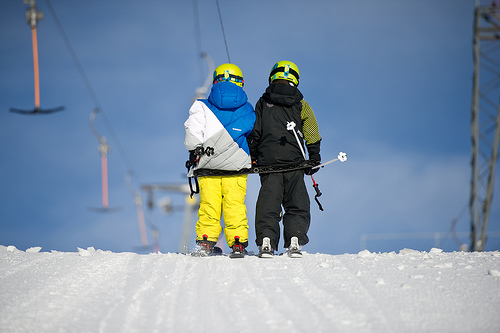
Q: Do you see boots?
A: Yes, there are boots.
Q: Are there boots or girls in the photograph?
A: Yes, there are boots.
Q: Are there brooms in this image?
A: No, there are no brooms.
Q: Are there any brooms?
A: No, there are no brooms.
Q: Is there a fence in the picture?
A: No, there are no fences.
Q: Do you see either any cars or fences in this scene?
A: No, there are no fences or cars.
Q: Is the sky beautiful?
A: Yes, the sky is beautiful.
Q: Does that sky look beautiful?
A: Yes, the sky is beautiful.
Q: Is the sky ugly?
A: No, the sky is beautiful.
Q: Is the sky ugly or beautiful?
A: The sky is beautiful.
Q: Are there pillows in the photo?
A: No, there are no pillows.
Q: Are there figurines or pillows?
A: No, there are no pillows or figurines.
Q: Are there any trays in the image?
A: No, there are no trays.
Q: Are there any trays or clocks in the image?
A: No, there are no trays or clocks.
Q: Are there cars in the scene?
A: No, there are no cars.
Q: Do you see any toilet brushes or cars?
A: No, there are no cars or toilet brushes.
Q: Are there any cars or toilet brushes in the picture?
A: No, there are no cars or toilet brushes.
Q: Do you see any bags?
A: No, there are no bags.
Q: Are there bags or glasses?
A: No, there are no bags or glasses.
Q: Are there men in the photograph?
A: No, there are no men.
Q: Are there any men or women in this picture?
A: No, there are no men or women.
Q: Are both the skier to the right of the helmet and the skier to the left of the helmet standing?
A: Yes, both the skier and the skier are standing.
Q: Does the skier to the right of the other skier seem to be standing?
A: Yes, the skier is standing.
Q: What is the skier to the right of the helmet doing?
A: The skier is standing.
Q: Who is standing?
A: The skier is standing.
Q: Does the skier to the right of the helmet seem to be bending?
A: No, the skier is standing.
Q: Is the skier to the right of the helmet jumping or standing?
A: The skier is standing.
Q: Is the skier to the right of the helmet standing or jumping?
A: The skier is standing.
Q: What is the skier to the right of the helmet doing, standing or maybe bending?
A: The skier is standing.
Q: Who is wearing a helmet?
A: The skier is wearing a helmet.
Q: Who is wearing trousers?
A: The skier is wearing trousers.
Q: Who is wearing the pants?
A: The skier is wearing trousers.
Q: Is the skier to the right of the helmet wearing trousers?
A: Yes, the skier is wearing trousers.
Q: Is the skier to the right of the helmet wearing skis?
A: No, the skier is wearing trousers.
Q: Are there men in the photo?
A: No, there are no men.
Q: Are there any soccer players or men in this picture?
A: No, there are no men or soccer players.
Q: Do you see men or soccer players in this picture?
A: No, there are no men or soccer players.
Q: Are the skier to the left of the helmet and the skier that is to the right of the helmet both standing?
A: Yes, both the skier and the skier are standing.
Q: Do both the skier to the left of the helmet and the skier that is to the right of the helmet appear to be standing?
A: Yes, both the skier and the skier are standing.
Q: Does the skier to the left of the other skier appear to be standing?
A: Yes, the skier is standing.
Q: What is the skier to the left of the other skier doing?
A: The skier is standing.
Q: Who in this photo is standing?
A: The skier is standing.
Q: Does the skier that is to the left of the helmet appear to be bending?
A: No, the skier is standing.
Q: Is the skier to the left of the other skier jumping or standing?
A: The skier is standing.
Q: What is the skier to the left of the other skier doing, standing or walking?
A: The skier is standing.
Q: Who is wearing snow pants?
A: The skier is wearing snow pants.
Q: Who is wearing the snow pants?
A: The skier is wearing snow pants.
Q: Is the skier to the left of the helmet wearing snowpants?
A: Yes, the skier is wearing snowpants.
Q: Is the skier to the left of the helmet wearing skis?
A: No, the skier is wearing snowpants.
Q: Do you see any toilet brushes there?
A: No, there are no toilet brushes.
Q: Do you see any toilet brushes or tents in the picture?
A: No, there are no toilet brushes or tents.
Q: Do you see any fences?
A: No, there are no fences.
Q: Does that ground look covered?
A: Yes, the ground is covered.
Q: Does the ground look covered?
A: Yes, the ground is covered.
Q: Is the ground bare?
A: No, the ground is covered.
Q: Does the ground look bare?
A: No, the ground is covered.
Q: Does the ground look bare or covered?
A: The ground is covered.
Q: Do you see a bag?
A: No, there are no bags.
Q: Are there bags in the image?
A: No, there are no bags.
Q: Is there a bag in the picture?
A: No, there are no bags.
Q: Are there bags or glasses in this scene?
A: No, there are no bags or glasses.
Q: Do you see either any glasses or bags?
A: No, there are no bags or glasses.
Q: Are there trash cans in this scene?
A: No, there are no trash cans.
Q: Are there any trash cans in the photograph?
A: No, there are no trash cans.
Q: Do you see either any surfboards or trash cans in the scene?
A: No, there are no trash cans or surfboards.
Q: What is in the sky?
A: The clouds are in the sky.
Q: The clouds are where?
A: The clouds are in the sky.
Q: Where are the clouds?
A: The clouds are in the sky.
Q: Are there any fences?
A: No, there are no fences.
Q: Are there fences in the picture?
A: No, there are no fences.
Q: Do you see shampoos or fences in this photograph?
A: No, there are no fences or shampoos.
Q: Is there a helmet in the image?
A: Yes, there is a helmet.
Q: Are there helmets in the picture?
A: Yes, there is a helmet.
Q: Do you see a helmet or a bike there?
A: Yes, there is a helmet.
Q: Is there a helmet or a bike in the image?
A: Yes, there is a helmet.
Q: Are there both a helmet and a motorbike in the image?
A: No, there is a helmet but no motorcycles.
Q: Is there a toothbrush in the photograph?
A: No, there are no toothbrushes.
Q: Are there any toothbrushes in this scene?
A: No, there are no toothbrushes.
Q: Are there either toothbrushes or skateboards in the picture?
A: No, there are no toothbrushes or skateboards.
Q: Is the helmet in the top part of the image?
A: Yes, the helmet is in the top of the image.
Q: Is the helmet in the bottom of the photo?
A: No, the helmet is in the top of the image.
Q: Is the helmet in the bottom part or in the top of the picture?
A: The helmet is in the top of the image.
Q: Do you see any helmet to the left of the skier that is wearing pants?
A: Yes, there is a helmet to the left of the skier.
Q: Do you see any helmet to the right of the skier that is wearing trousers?
A: No, the helmet is to the left of the skier.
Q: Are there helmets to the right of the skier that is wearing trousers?
A: No, the helmet is to the left of the skier.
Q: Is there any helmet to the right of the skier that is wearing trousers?
A: No, the helmet is to the left of the skier.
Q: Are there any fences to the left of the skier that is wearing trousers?
A: No, there is a helmet to the left of the skier.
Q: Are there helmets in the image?
A: Yes, there is a helmet.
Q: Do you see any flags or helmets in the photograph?
A: Yes, there is a helmet.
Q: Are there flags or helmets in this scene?
A: Yes, there is a helmet.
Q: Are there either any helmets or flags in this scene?
A: Yes, there is a helmet.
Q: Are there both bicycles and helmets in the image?
A: No, there is a helmet but no bicycles.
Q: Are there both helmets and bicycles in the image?
A: No, there is a helmet but no bicycles.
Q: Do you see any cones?
A: No, there are no cones.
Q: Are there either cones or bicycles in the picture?
A: No, there are no cones or bicycles.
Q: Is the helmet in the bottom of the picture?
A: No, the helmet is in the top of the image.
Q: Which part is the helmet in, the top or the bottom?
A: The helmet is in the top of the image.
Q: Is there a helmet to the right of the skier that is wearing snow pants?
A: Yes, there is a helmet to the right of the skier.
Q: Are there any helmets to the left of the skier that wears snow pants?
A: No, the helmet is to the right of the skier.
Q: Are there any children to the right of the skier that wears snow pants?
A: No, there is a helmet to the right of the skier.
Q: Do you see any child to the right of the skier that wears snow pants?
A: No, there is a helmet to the right of the skier.